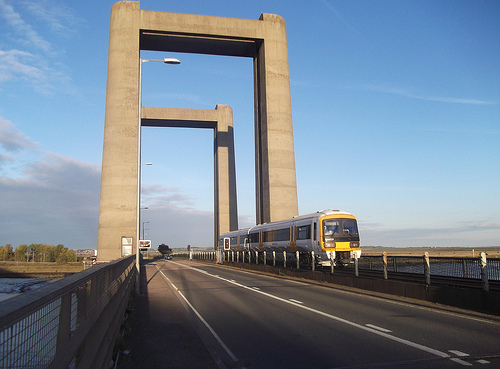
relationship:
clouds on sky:
[323, 61, 431, 118] [7, 4, 499, 239]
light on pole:
[128, 43, 189, 70] [122, 51, 150, 188]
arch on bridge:
[90, 4, 312, 266] [23, 2, 475, 349]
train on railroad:
[213, 206, 359, 262] [166, 208, 500, 293]